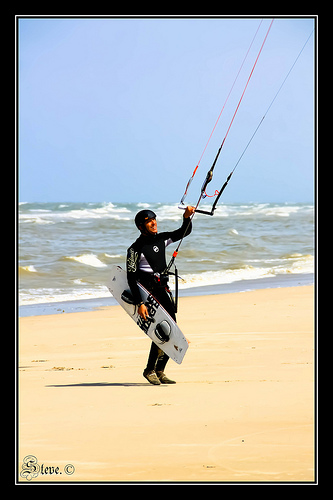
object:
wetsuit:
[121, 215, 194, 374]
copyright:
[19, 454, 76, 485]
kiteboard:
[102, 262, 190, 368]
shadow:
[42, 379, 165, 393]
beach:
[18, 282, 315, 484]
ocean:
[15, 200, 315, 313]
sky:
[19, 19, 315, 206]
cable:
[192, 17, 278, 209]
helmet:
[132, 207, 156, 228]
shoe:
[141, 368, 161, 388]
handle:
[176, 205, 219, 219]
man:
[124, 204, 198, 389]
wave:
[255, 205, 304, 217]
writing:
[132, 293, 161, 336]